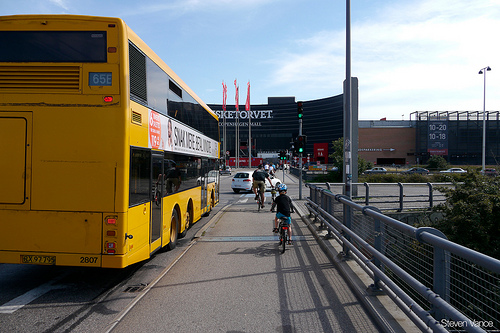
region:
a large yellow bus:
[1, 8, 236, 260]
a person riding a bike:
[263, 182, 315, 252]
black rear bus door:
[143, 152, 168, 244]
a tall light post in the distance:
[468, 67, 497, 172]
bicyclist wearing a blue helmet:
[271, 175, 293, 197]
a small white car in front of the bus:
[233, 162, 288, 204]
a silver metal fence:
[306, 180, 438, 287]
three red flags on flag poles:
[213, 82, 257, 152]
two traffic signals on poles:
[286, 95, 311, 197]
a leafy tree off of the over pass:
[441, 175, 498, 304]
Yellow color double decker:
[5, 12, 215, 267]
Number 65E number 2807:
[72, 63, 124, 266]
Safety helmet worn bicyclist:
[268, 178, 300, 256]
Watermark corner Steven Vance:
[417, 315, 499, 330]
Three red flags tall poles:
[215, 76, 257, 171]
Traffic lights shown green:
[287, 108, 307, 202]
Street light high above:
[470, 59, 495, 175]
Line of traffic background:
[360, 161, 496, 178]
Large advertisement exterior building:
[407, 108, 464, 161]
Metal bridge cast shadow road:
[257, 235, 497, 331]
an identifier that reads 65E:
[90, 69, 114, 88]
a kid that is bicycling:
[267, 178, 296, 256]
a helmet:
[275, 181, 290, 191]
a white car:
[230, 161, 288, 196]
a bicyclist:
[247, 155, 270, 216]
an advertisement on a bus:
[140, 100, 225, 161]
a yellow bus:
[0, 10, 220, 310]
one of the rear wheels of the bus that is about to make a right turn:
[160, 201, 185, 248]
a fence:
[297, 180, 492, 330]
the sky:
[1, 0, 498, 122]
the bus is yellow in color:
[0, 14, 219, 289]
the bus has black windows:
[128, 40, 222, 148]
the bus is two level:
[0, 12, 224, 269]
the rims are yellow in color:
[168, 217, 178, 242]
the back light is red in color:
[101, 93, 115, 103]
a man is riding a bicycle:
[252, 160, 268, 212]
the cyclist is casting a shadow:
[219, 237, 289, 262]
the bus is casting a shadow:
[1, 251, 171, 312]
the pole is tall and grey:
[343, 2, 357, 258]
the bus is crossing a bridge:
[3, 193, 496, 331]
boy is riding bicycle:
[261, 172, 306, 262]